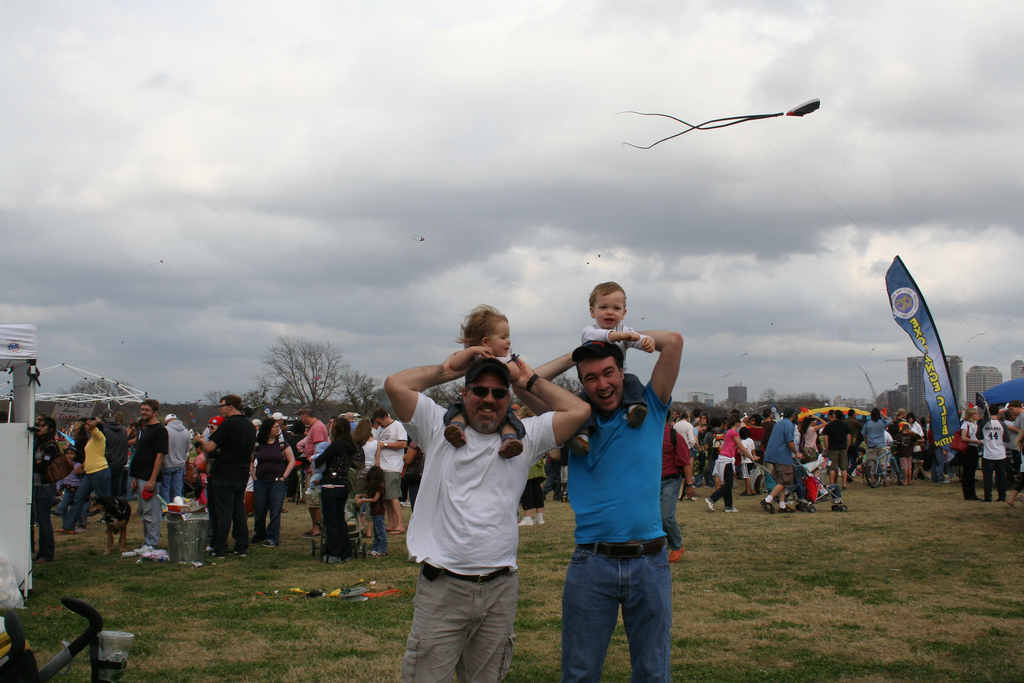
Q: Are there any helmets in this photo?
A: No, there are no helmets.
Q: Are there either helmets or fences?
A: No, there are no helmets or fences.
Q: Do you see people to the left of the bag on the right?
A: Yes, there is a person to the left of the bag.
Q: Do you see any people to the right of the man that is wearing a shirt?
A: Yes, there is a person to the right of the man.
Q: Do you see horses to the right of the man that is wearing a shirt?
A: No, there is a person to the right of the man.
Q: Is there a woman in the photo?
A: Yes, there is a woman.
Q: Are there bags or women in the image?
A: Yes, there is a woman.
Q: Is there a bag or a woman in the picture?
A: Yes, there is a woman.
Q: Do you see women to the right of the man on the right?
A: Yes, there is a woman to the right of the man.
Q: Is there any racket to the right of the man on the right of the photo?
A: No, there is a woman to the right of the man.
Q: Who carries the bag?
A: The woman carries the bag.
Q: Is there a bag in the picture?
A: Yes, there is a bag.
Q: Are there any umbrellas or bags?
A: Yes, there is a bag.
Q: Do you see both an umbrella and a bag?
A: No, there is a bag but no umbrellas.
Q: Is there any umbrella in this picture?
A: No, there are no umbrellas.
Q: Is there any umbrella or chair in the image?
A: No, there are no umbrellas or chairs.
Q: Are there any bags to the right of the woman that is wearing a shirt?
A: Yes, there is a bag to the right of the woman.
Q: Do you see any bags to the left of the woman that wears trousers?
A: No, the bag is to the right of the woman.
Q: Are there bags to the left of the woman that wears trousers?
A: No, the bag is to the right of the woman.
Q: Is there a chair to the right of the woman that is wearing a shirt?
A: No, there is a bag to the right of the woman.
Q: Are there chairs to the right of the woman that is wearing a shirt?
A: No, there is a bag to the right of the woman.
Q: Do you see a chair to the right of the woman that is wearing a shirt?
A: No, there is a bag to the right of the woman.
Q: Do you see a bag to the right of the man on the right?
A: Yes, there is a bag to the right of the man.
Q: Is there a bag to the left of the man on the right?
A: No, the bag is to the right of the man.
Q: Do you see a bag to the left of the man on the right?
A: No, the bag is to the right of the man.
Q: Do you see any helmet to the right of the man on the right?
A: No, there is a bag to the right of the man.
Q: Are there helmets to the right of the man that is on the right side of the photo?
A: No, there is a bag to the right of the man.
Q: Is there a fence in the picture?
A: No, there are no fences.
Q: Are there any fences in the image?
A: No, there are no fences.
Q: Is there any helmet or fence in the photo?
A: No, there are no fences or helmets.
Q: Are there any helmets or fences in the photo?
A: No, there are no fences or helmets.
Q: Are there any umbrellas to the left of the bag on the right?
A: No, there is a man to the left of the bag.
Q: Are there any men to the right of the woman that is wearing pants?
A: Yes, there is a man to the right of the woman.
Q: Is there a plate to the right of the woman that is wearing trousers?
A: No, there is a man to the right of the woman.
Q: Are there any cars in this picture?
A: No, there are no cars.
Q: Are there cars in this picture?
A: No, there are no cars.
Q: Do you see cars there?
A: No, there are no cars.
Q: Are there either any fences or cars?
A: No, there are no cars or fences.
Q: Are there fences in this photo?
A: No, there are no fences.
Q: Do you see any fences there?
A: No, there are no fences.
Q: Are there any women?
A: Yes, there is a woman.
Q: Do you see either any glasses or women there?
A: Yes, there is a woman.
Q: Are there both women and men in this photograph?
A: Yes, there are both a woman and a man.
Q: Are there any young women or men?
A: Yes, there is a young woman.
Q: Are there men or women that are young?
A: Yes, the woman is young.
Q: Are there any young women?
A: Yes, there is a young woman.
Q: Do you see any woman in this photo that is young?
A: Yes, there is a woman that is young.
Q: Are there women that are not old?
A: Yes, there is an young woman.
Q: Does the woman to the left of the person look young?
A: Yes, the woman is young.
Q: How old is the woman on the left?
A: The woman is young.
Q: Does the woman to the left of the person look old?
A: No, the woman is young.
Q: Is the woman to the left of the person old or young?
A: The woman is young.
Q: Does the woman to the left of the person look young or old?
A: The woman is young.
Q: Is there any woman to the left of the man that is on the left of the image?
A: Yes, there is a woman to the left of the man.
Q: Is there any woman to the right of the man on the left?
A: No, the woman is to the left of the man.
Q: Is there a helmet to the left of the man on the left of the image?
A: No, there is a woman to the left of the man.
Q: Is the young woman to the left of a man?
A: Yes, the woman is to the left of a man.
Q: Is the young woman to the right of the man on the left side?
A: No, the woman is to the left of the man.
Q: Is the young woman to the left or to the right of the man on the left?
A: The woman is to the left of the man.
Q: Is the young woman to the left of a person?
A: Yes, the woman is to the left of a person.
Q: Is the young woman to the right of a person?
A: No, the woman is to the left of a person.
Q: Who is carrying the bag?
A: The woman is carrying the bag.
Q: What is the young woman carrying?
A: The woman is carrying a bag.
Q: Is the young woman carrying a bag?
A: Yes, the woman is carrying a bag.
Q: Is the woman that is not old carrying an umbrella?
A: No, the woman is carrying a bag.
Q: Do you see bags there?
A: Yes, there is a bag.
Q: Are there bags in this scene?
A: Yes, there is a bag.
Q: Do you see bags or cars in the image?
A: Yes, there is a bag.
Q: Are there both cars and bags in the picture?
A: No, there is a bag but no cars.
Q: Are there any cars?
A: No, there are no cars.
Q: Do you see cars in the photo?
A: No, there are no cars.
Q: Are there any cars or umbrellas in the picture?
A: No, there are no cars or umbrellas.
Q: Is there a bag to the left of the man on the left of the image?
A: Yes, there is a bag to the left of the man.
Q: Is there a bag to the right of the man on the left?
A: No, the bag is to the left of the man.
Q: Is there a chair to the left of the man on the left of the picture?
A: No, there is a bag to the left of the man.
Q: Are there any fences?
A: No, there are no fences.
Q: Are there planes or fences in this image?
A: No, there are no fences or planes.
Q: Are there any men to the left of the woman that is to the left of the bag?
A: Yes, there is a man to the left of the woman.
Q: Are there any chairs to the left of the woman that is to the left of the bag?
A: No, there is a man to the left of the woman.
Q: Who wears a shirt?
A: The man wears a shirt.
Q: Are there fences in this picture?
A: No, there are no fences.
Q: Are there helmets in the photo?
A: No, there are no helmets.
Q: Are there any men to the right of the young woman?
A: Yes, there is a man to the right of the woman.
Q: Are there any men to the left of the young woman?
A: No, the man is to the right of the woman.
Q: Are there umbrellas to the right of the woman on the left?
A: No, there is a man to the right of the woman.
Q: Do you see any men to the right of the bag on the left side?
A: Yes, there is a man to the right of the bag.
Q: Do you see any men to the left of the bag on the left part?
A: No, the man is to the right of the bag.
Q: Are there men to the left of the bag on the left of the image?
A: No, the man is to the right of the bag.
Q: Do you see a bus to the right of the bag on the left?
A: No, there is a man to the right of the bag.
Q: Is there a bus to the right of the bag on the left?
A: No, there is a man to the right of the bag.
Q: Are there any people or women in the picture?
A: Yes, there is a woman.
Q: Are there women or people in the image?
A: Yes, there is a woman.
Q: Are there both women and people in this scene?
A: Yes, there are both a woman and a person.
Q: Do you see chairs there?
A: No, there are no chairs.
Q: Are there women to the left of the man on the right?
A: Yes, there is a woman to the left of the man.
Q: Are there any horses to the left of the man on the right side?
A: No, there is a woman to the left of the man.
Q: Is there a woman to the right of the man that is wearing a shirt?
A: Yes, there is a woman to the right of the man.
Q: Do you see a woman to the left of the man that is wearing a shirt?
A: No, the woman is to the right of the man.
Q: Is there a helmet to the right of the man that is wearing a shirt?
A: No, there is a woman to the right of the man.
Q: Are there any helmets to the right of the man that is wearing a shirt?
A: No, there is a woman to the right of the man.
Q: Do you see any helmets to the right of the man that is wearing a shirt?
A: No, there is a woman to the right of the man.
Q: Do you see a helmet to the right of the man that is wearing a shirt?
A: No, there is a woman to the right of the man.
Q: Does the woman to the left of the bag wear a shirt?
A: Yes, the woman wears a shirt.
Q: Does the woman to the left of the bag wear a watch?
A: No, the woman wears a shirt.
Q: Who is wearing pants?
A: The woman is wearing pants.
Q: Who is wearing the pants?
A: The woman is wearing pants.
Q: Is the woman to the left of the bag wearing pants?
A: Yes, the woman is wearing pants.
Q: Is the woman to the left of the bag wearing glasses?
A: No, the woman is wearing pants.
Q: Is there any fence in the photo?
A: No, there are no fences.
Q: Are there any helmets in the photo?
A: No, there are no helmets.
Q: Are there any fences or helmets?
A: No, there are no helmets or fences.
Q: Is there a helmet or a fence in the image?
A: No, there are no helmets or fences.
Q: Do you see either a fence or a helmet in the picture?
A: No, there are no helmets or fences.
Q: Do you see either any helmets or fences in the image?
A: No, there are no helmets or fences.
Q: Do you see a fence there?
A: No, there are no fences.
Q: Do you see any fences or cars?
A: No, there are no fences or cars.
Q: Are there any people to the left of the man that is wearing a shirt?
A: Yes, there is a person to the left of the man.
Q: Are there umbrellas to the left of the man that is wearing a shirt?
A: No, there is a person to the left of the man.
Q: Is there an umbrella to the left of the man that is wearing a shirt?
A: No, there is a person to the left of the man.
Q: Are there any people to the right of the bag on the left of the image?
A: Yes, there is a person to the right of the bag.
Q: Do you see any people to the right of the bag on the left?
A: Yes, there is a person to the right of the bag.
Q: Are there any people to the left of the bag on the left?
A: No, the person is to the right of the bag.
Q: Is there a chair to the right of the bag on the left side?
A: No, there is a person to the right of the bag.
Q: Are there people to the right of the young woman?
A: Yes, there is a person to the right of the woman.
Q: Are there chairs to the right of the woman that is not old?
A: No, there is a person to the right of the woman.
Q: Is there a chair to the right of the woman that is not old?
A: No, there is a person to the right of the woman.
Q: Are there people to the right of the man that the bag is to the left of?
A: Yes, there is a person to the right of the man.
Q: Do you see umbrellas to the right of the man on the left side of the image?
A: No, there is a person to the right of the man.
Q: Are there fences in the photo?
A: No, there are no fences.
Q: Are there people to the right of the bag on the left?
A: Yes, there is a person to the right of the bag.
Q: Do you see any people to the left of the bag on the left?
A: No, the person is to the right of the bag.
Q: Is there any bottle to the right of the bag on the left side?
A: No, there is a person to the right of the bag.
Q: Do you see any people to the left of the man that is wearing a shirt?
A: Yes, there is a person to the left of the man.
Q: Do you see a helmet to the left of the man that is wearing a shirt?
A: No, there is a person to the left of the man.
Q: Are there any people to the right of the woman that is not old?
A: Yes, there is a person to the right of the woman.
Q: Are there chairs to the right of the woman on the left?
A: No, there is a person to the right of the woman.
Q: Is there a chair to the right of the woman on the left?
A: No, there is a person to the right of the woman.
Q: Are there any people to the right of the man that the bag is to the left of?
A: Yes, there is a person to the right of the man.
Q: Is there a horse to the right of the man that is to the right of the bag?
A: No, there is a person to the right of the man.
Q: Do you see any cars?
A: No, there are no cars.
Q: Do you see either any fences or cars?
A: No, there are no cars or fences.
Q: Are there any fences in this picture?
A: No, there are no fences.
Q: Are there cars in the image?
A: No, there are no cars.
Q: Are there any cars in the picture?
A: No, there are no cars.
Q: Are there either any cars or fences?
A: No, there are no cars or fences.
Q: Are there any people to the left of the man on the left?
A: Yes, there is a person to the left of the man.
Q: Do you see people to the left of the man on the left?
A: Yes, there is a person to the left of the man.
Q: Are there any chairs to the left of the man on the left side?
A: No, there is a person to the left of the man.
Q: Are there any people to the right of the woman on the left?
A: Yes, there is a person to the right of the woman.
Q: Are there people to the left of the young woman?
A: No, the person is to the right of the woman.